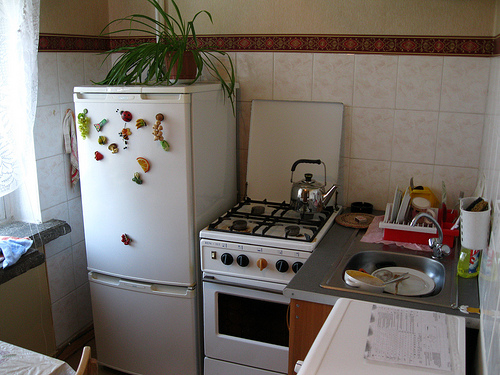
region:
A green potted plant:
[99, 2, 240, 92]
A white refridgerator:
[67, 85, 205, 371]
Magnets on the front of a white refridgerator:
[75, 106, 184, 191]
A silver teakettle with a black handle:
[285, 158, 336, 222]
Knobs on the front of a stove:
[201, 240, 303, 285]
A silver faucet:
[406, 211, 451, 266]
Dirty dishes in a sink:
[322, 237, 455, 314]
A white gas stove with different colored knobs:
[192, 186, 310, 372]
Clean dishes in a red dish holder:
[362, 170, 459, 250]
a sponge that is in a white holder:
[456, 192, 495, 259]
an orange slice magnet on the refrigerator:
[134, 152, 160, 174]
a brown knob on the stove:
[251, 251, 276, 282]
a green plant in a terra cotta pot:
[136, 4, 210, 82]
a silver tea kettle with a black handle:
[291, 152, 340, 211]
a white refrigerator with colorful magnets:
[69, 90, 202, 373]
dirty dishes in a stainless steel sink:
[343, 259, 426, 298]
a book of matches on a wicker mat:
[349, 207, 369, 225]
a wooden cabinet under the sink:
[291, 301, 317, 332]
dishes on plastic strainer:
[391, 182, 451, 235]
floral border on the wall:
[320, 30, 487, 57]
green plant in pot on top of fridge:
[98, 1, 256, 126]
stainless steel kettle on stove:
[287, 138, 342, 233]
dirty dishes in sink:
[333, 238, 440, 328]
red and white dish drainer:
[370, 174, 474, 277]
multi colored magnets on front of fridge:
[68, 97, 191, 259]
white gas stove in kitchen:
[192, 180, 323, 374]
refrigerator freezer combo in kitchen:
[51, 65, 222, 367]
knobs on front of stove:
[205, 239, 325, 289]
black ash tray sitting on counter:
[346, 189, 381, 215]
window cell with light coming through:
[0, 151, 72, 296]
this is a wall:
[361, 90, 470, 172]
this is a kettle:
[290, 172, 327, 208]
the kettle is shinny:
[298, 187, 310, 199]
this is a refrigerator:
[79, 107, 184, 314]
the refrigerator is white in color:
[140, 204, 182, 276]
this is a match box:
[356, 212, 366, 222]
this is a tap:
[411, 212, 451, 262]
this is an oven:
[207, 281, 274, 359]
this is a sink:
[358, 250, 443, 294]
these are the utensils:
[388, 186, 446, 215]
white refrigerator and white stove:
[59, 67, 336, 374]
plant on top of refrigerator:
[92, 16, 202, 273]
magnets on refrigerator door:
[72, 90, 187, 275]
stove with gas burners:
[202, 191, 322, 368]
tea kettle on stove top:
[254, 153, 347, 238]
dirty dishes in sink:
[335, 209, 483, 337]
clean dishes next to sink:
[380, 167, 487, 282]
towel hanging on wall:
[52, 87, 117, 214]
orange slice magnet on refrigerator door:
[133, 147, 178, 198]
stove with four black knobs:
[203, 190, 322, 325]